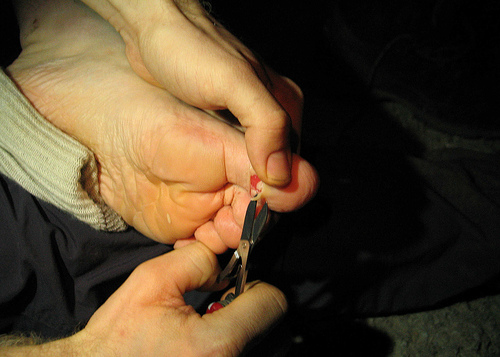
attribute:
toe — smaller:
[230, 187, 260, 226]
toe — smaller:
[208, 204, 245, 243]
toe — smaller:
[189, 223, 226, 253]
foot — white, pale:
[135, 62, 295, 284]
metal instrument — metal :
[197, 195, 269, 316]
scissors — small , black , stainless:
[208, 195, 290, 313]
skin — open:
[0, 4, 327, 354]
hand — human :
[85, 238, 281, 355]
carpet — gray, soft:
[346, 295, 467, 354]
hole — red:
[249, 174, 264, 189]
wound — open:
[243, 167, 265, 207]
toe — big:
[226, 127, 315, 214]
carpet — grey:
[332, 287, 499, 353]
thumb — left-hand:
[234, 76, 295, 188]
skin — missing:
[248, 171, 263, 200]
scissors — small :
[195, 200, 267, 323]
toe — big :
[225, 129, 325, 209]